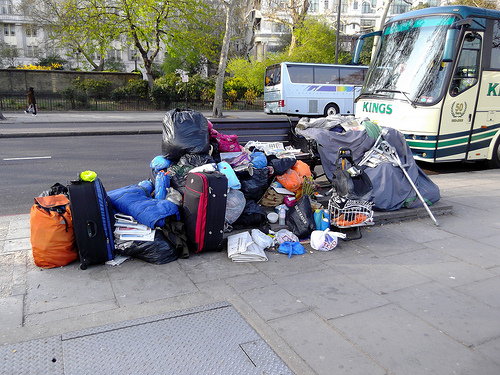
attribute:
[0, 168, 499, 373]
sidewalk — grey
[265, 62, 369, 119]
bus — white, parked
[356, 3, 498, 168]
bus — parked, blue, white, blue topped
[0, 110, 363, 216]
road — grey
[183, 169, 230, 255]
suitcase — black, red, pink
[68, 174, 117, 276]
suitcase — black, blue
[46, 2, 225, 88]
tree — green, brown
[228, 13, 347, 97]
tree — green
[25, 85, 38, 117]
person — walking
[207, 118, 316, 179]
bench — brown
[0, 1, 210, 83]
building — white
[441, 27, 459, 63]
side view mirror — side view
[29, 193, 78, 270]
bag — orange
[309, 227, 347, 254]
bag — white, plastic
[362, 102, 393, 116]
writing — green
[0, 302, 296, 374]
grate — metal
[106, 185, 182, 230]
coat — blue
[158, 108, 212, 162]
trash bag — large, black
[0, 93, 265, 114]
fence — metal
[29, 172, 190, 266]
stuff — random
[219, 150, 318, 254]
stuff — random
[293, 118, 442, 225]
stuff — random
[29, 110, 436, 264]
pile — random